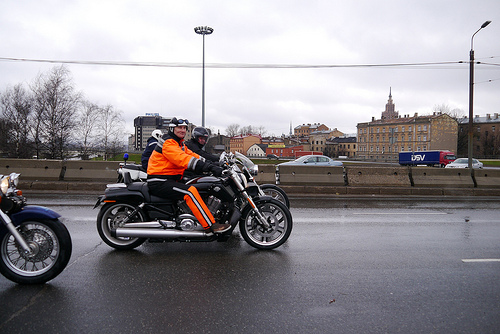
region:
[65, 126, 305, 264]
man on bike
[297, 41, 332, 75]
white clouds in blue sky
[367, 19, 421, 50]
white clouds in blue sky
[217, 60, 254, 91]
white clouds in blue sky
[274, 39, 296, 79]
white clouds in blue sky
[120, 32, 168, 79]
white clouds in blue sky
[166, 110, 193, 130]
helmet with goggles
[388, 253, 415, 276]
part of the highway road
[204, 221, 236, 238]
shoe of man riding bike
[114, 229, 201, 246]
exhaust of the motorcycle on road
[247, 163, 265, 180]
light of motorcycle on road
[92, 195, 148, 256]
back wheel of motorcycle on road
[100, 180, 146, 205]
back seat to motorcycle on road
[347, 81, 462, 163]
tan building outside of road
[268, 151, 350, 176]
car driving in opposite direction of motorcycle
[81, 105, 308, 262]
man on bike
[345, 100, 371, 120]
white clouds in blue sky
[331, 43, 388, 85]
white clouds in blue sky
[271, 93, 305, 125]
white clouds in blue sky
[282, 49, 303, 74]
white clouds in blue sky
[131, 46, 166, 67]
white clouds in blue sky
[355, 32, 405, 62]
white clouds in blue sky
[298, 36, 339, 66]
white clouds in blue sky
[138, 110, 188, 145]
man has white helmet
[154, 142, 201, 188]
man has orange jacket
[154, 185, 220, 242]
black and orange pants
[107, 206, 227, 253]
chrome pipe on bike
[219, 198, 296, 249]
black wheel on bike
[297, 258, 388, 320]
grey and wet road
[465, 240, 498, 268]
white line on road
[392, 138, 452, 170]
red and blue truck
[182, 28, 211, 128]
light pole behind man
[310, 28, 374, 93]
grey and cloudy sky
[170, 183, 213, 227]
a reflective stripe on the pants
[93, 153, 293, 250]
a motorcycle on the road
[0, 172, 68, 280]
the front end of a motorcycle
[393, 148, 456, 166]
a blue semi truck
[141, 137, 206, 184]
the jacket is orange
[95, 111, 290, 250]
two men riding next to each other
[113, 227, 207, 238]
the exhaust pipe is silver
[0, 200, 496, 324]
the asphalt is wet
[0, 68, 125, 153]
the tree branches are bare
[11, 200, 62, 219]
the fender is blue